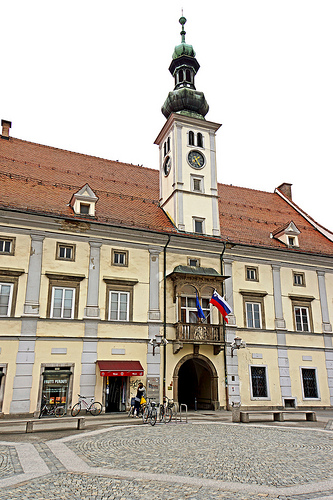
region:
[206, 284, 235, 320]
The flag is red, blue, and white.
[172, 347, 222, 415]
The doorway is arched.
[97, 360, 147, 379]
The awning is red.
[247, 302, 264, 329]
The window is closed.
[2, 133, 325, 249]
The roof is brown.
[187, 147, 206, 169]
The clock hands are yellow.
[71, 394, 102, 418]
Nobody is riding the bike.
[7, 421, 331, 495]
The road is very interesting.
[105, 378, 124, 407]
The door is open.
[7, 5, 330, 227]
The sky is hazy.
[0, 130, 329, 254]
The roof of a building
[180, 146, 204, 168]
The clock is round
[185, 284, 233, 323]
Two flags on a building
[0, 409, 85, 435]
A long bench is sitting empty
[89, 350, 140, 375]
The awning is red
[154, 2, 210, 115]
The top of a tower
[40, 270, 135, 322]
Two windows of a building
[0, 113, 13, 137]
A chimney on a roof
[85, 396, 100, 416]
A round black bicycle wheel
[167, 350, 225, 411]
A tunnel leading into a building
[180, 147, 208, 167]
clock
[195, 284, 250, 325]
flag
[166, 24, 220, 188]
tan clock tower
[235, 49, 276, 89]
white clouds in blue sky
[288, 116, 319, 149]
white clouds in blue sky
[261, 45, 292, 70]
white clouds in blue sky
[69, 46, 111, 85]
white clouds in blue sky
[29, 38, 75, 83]
white clouds in blue sky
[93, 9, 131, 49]
white clouds in blue sky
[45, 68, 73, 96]
white clouds in blue sky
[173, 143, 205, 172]
clock in tower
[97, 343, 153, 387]
red awning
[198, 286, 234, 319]
red white and blue flag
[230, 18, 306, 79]
white clouds in blue sky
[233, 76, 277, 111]
white clouds in blue sky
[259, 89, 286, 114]
white clouds in blue sky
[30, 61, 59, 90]
white clouds in blue sky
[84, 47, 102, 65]
white clouds in blue sky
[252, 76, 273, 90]
white clouds in blue sky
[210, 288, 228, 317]
flag flying from building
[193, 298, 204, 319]
blue flag flying from building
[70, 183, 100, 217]
window sticking from roof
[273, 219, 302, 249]
window sticking from roof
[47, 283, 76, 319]
window in yellow wall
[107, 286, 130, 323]
window in yellow wall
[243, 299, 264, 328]
window in yellow wall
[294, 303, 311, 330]
window in yellow wall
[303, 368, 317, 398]
window in yellow wall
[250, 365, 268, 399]
window in yellow wall